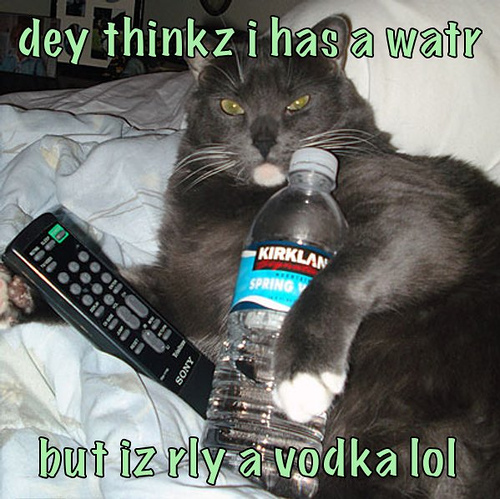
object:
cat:
[0, 13, 499, 497]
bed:
[0, 0, 499, 497]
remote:
[0, 210, 215, 421]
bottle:
[196, 146, 350, 499]